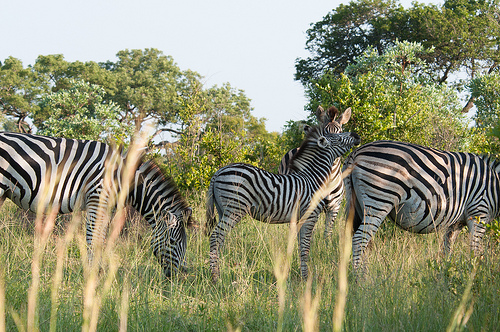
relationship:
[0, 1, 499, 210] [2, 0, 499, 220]
leaves on trees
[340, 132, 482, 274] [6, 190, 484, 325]
zebra in grass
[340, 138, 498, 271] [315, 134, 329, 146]
zebra has ear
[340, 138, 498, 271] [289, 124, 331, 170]
zebra has mane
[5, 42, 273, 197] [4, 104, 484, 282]
tree behind zebras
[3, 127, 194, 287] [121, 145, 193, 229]
zebra has mane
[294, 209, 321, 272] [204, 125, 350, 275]
leg of zebra